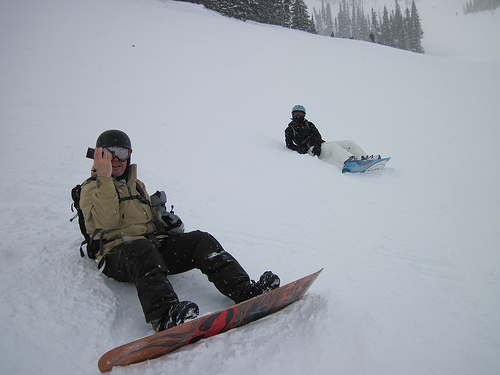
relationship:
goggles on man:
[100, 145, 133, 161] [78, 130, 282, 332]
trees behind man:
[174, 0, 499, 53] [78, 130, 282, 332]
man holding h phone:
[78, 130, 282, 332] [85, 148, 105, 159]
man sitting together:
[64, 130, 281, 331] [79, 105, 381, 332]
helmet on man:
[96, 129, 132, 154] [78, 130, 282, 332]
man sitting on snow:
[64, 130, 281, 331] [0, 0, 499, 374]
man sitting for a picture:
[78, 130, 282, 332] [1, 1, 500, 374]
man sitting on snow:
[78, 130, 282, 332] [0, 0, 499, 374]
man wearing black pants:
[78, 130, 282, 332] [98, 210, 252, 324]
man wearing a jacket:
[78, 130, 282, 332] [79, 165, 169, 267]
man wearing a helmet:
[78, 130, 282, 332] [96, 129, 132, 154]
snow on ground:
[0, 0, 499, 374] [0, 1, 499, 374]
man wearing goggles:
[78, 130, 282, 332] [100, 145, 133, 161]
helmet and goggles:
[96, 129, 132, 154] [100, 145, 133, 161]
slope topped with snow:
[0, 1, 499, 374] [0, 0, 499, 374]